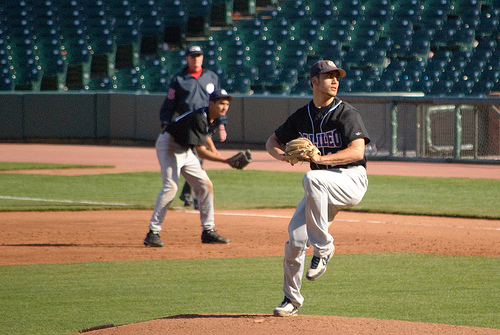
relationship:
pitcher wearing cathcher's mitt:
[264, 61, 370, 315] [282, 137, 321, 165]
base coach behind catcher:
[157, 45, 221, 132] [141, 90, 252, 248]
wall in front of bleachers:
[1, 91, 498, 161] [1, 1, 498, 98]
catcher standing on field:
[141, 90, 252, 248] [2, 139, 499, 334]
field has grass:
[2, 139, 499, 334] [0, 162, 499, 220]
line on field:
[1, 193, 499, 237] [2, 139, 499, 334]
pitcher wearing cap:
[264, 61, 370, 315] [309, 58, 345, 79]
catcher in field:
[141, 90, 252, 248] [2, 139, 499, 334]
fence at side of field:
[390, 99, 499, 156] [2, 139, 499, 334]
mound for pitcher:
[74, 312, 499, 335] [264, 61, 370, 315]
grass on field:
[0, 162, 499, 220] [2, 139, 499, 334]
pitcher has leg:
[264, 61, 370, 315] [299, 169, 366, 277]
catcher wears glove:
[141, 90, 252, 248] [228, 148, 253, 170]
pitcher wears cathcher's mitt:
[264, 61, 370, 315] [282, 137, 321, 165]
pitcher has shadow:
[264, 61, 370, 315] [79, 312, 277, 334]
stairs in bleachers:
[25, 2, 283, 93] [1, 1, 498, 98]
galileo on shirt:
[300, 131, 347, 152] [273, 97, 370, 168]